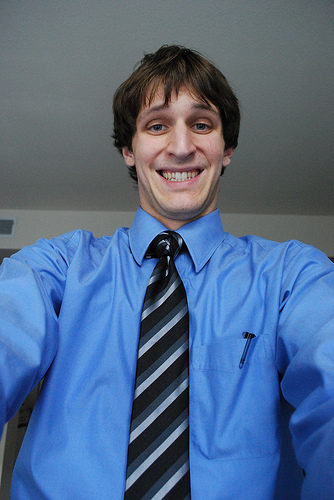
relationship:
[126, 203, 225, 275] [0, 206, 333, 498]
collar of blue shirt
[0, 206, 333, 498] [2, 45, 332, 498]
blue shirt of man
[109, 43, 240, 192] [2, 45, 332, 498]
hair of man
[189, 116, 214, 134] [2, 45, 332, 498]
eye of man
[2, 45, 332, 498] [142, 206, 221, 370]
man wearing necktie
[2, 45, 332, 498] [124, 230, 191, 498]
man wearing necktie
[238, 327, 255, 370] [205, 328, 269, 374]
pen hanging from pocket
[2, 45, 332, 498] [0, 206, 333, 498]
man in a blue shirt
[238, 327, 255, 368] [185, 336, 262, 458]
pen in pocket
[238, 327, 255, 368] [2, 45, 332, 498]
pen of man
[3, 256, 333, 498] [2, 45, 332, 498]
wall behind man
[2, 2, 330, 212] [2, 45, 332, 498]
ceiling behind man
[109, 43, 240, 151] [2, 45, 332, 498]
hair on man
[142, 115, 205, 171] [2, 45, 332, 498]
nose on man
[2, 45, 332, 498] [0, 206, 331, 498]
man wearing a blue shirt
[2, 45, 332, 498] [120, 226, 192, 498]
man wearing tie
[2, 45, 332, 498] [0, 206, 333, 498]
man wearing blue shirt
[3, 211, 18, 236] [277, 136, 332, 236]
air vent on wall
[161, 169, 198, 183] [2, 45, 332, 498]
teeth on man